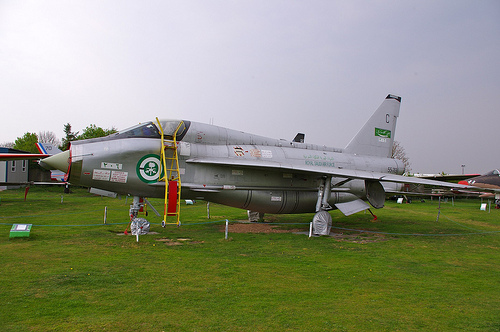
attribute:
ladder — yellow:
[159, 132, 181, 226]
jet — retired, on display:
[30, 96, 497, 265]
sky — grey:
[254, 62, 336, 109]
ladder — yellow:
[155, 115, 184, 227]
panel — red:
[165, 177, 176, 214]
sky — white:
[2, 2, 498, 151]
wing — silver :
[209, 156, 497, 196]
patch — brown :
[182, 216, 352, 239]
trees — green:
[14, 120, 122, 156]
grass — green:
[0, 185, 499, 330]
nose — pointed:
[39, 145, 69, 175]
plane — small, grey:
[34, 91, 484, 239]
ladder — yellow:
[156, 125, 187, 227]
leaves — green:
[14, 132, 39, 151]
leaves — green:
[57, 121, 117, 150]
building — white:
[2, 140, 59, 187]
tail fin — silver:
[349, 87, 405, 155]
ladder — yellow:
[153, 117, 188, 234]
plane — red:
[435, 175, 498, 199]